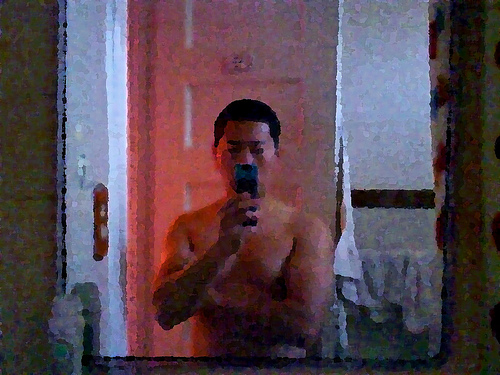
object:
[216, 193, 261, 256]
hand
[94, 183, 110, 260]
box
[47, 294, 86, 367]
bottle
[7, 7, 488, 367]
photo filter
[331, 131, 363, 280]
shirt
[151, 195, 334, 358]
body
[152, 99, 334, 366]
man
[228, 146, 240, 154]
eye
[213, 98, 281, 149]
black hair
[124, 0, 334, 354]
door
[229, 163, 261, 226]
cell phone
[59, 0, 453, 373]
mirror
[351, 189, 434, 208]
trim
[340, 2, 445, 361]
wall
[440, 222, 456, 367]
rim